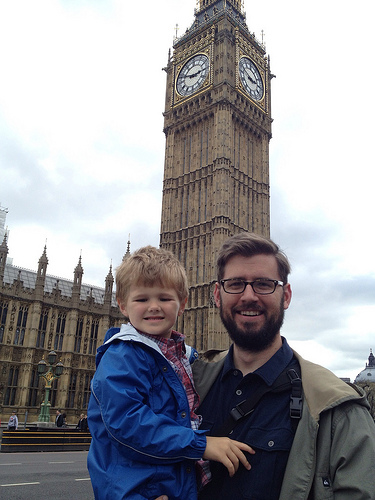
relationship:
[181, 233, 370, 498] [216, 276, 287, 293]
man wearing eyeglasses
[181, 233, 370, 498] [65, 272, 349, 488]
man in foreground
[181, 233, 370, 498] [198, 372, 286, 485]
man wearing blue shirt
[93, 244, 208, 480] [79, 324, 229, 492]
boy wearing jacket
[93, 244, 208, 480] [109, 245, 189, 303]
boy has blonde hair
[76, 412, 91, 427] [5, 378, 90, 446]
person in background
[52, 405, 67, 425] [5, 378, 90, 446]
person in background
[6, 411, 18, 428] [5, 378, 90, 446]
person in background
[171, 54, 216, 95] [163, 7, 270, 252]
clock on building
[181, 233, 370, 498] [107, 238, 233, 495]
man holding boy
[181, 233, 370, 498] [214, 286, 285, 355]
man has beard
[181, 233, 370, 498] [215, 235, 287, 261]
man has hair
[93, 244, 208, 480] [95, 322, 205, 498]
boy wearing blue jacket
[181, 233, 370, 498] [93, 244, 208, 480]
man holding boy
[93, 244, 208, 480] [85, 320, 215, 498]
boy wearing coat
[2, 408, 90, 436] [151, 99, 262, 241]
people before building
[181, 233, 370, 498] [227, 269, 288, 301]
man wearing glasses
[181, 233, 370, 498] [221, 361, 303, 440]
man wearing straps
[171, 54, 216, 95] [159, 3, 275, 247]
clock on tower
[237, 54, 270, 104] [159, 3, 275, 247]
clock on tower